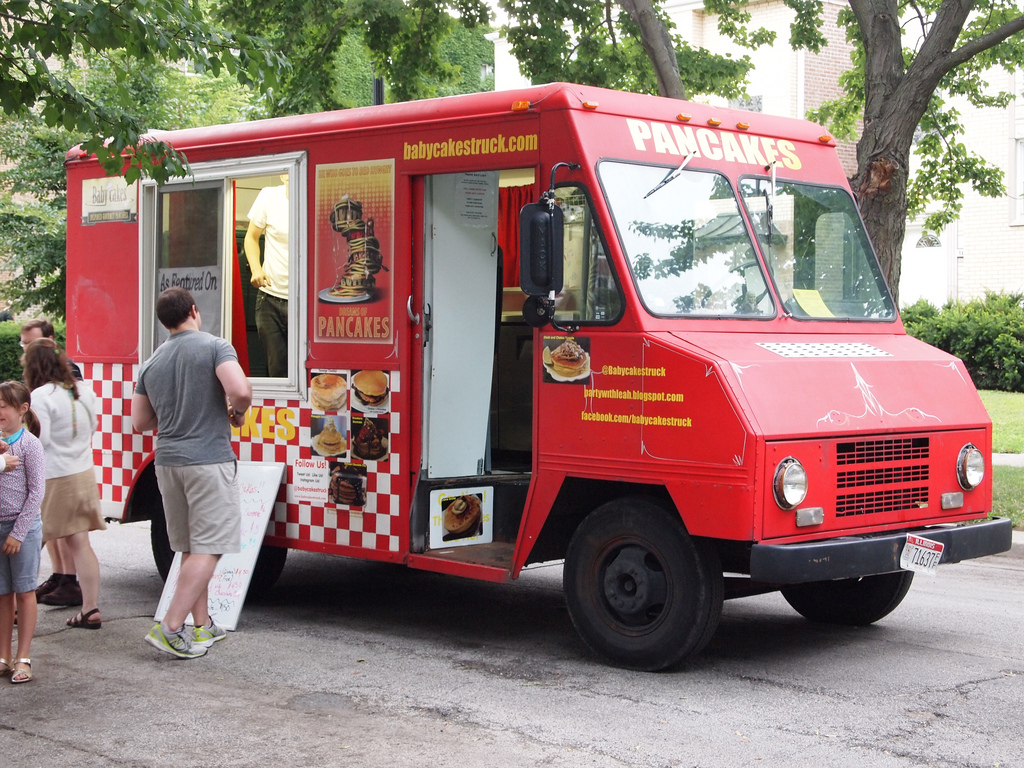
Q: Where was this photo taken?
A: City street.